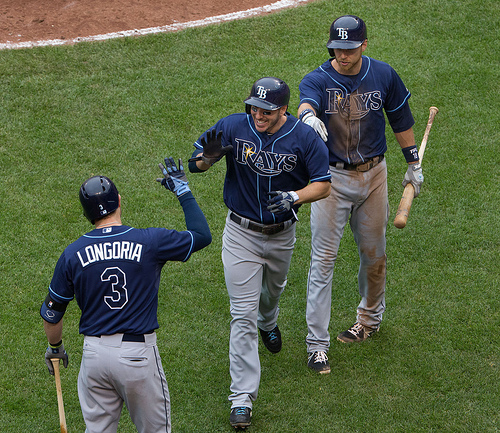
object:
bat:
[390, 102, 440, 232]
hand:
[401, 162, 425, 199]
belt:
[224, 206, 301, 237]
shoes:
[306, 344, 332, 377]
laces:
[313, 350, 328, 366]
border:
[0, 0, 314, 54]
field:
[0, 0, 500, 433]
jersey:
[293, 50, 414, 169]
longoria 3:
[73, 240, 144, 313]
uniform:
[295, 53, 416, 355]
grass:
[2, 0, 500, 433]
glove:
[298, 108, 329, 143]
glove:
[188, 127, 235, 168]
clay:
[0, 0, 306, 51]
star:
[242, 145, 257, 161]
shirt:
[193, 110, 333, 229]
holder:
[239, 218, 251, 231]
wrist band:
[400, 143, 421, 166]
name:
[74, 240, 144, 269]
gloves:
[155, 156, 191, 198]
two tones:
[166, 158, 191, 196]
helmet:
[319, 8, 379, 50]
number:
[99, 264, 131, 310]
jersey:
[47, 224, 195, 338]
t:
[335, 27, 344, 37]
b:
[339, 30, 348, 41]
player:
[295, 13, 426, 376]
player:
[186, 75, 333, 429]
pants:
[303, 156, 389, 355]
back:
[75, 227, 159, 343]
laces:
[266, 329, 277, 341]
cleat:
[335, 295, 407, 345]